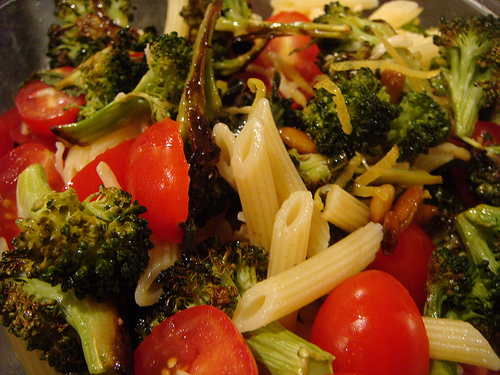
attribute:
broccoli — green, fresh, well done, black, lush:
[60, 192, 136, 283]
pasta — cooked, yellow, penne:
[225, 122, 306, 216]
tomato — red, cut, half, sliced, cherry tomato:
[133, 126, 185, 213]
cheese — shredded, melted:
[349, 172, 401, 205]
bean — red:
[376, 180, 437, 221]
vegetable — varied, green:
[271, 23, 371, 105]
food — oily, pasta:
[116, 79, 330, 250]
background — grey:
[6, 5, 55, 59]